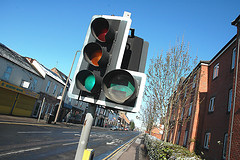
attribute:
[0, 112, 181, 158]
block — long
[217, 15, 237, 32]
clouds — white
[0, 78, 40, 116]
building — yellow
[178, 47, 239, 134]
building — large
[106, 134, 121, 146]
arrow — painted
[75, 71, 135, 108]
light — green, signal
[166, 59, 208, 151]
building — large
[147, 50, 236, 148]
building — large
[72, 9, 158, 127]
light — yellow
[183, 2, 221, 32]
sky — blue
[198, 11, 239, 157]
building — large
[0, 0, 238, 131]
sky — blue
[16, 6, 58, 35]
sky — blue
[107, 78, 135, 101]
arrow — green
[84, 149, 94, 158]
button — yellow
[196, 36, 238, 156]
building — large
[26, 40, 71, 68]
clouds — white 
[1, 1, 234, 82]
sky — blue 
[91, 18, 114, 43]
light — red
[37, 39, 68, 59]
clouds — white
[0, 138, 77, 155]
lines — white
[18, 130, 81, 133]
lines — white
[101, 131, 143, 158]
lines — white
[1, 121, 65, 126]
lines — white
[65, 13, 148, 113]
traffic light — red, yellow, green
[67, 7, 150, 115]
traffic signal — black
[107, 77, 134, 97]
arrow — green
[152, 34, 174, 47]
cloud — white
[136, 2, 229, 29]
sky — blue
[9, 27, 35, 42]
cloud — white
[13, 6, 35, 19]
cloud — white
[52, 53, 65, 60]
cloud — white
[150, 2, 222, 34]
sky — blue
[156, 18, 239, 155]
building — large